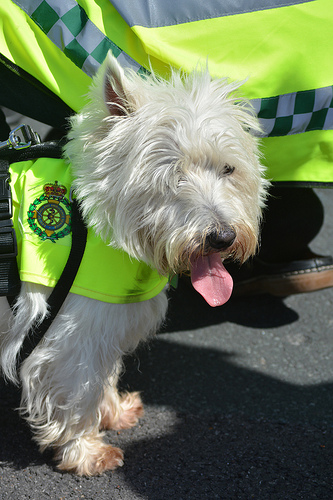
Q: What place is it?
A: It is a pavement.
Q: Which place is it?
A: It is a pavement.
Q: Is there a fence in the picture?
A: No, there are no fences.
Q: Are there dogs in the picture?
A: Yes, there is a dog.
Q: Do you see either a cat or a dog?
A: Yes, there is a dog.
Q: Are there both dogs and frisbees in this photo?
A: No, there is a dog but no frisbees.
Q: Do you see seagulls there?
A: No, there are no seagulls.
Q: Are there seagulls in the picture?
A: No, there are no seagulls.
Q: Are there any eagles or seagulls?
A: No, there are no seagulls or eagles.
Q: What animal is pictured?
A: The animal is a dog.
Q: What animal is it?
A: The animal is a dog.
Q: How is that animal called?
A: This is a dog.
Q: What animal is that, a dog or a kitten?
A: This is a dog.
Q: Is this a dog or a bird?
A: This is a dog.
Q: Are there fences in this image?
A: No, there are no fences.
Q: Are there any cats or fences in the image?
A: No, there are no fences or cats.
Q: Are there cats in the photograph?
A: No, there are no cats.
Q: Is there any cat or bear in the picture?
A: No, there are no cats or bears.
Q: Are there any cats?
A: No, there are no cats.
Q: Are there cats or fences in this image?
A: No, there are no cats or fences.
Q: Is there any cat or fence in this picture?
A: No, there are no cats or fences.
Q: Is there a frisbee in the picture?
A: No, there are no frisbees.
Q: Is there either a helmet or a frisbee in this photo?
A: No, there are no frisbees or helmets.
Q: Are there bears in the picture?
A: No, there are no bears.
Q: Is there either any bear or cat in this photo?
A: No, there are no bears or cats.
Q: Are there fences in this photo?
A: No, there are no fences.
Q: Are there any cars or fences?
A: No, there are no fences or cars.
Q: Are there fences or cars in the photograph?
A: No, there are no fences or cars.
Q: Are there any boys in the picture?
A: No, there are no boys.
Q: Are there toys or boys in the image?
A: No, there are no boys or toys.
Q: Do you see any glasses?
A: No, there are no glasses.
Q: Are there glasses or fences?
A: No, there are no glasses or fences.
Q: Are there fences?
A: No, there are no fences.